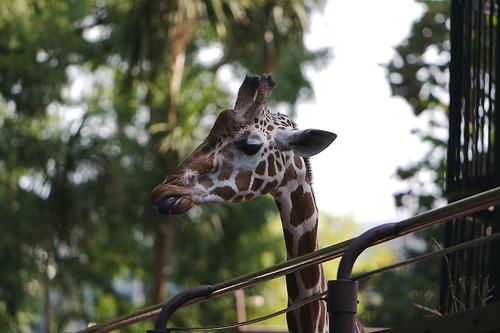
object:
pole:
[324, 220, 365, 332]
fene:
[1, 183, 498, 330]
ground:
[405, 115, 426, 137]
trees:
[1, 0, 336, 332]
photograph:
[0, 0, 500, 332]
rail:
[401, 175, 498, 236]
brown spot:
[235, 171, 253, 191]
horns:
[233, 75, 260, 111]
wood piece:
[233, 287, 249, 328]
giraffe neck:
[269, 185, 329, 333]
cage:
[435, 2, 498, 315]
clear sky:
[300, 0, 420, 219]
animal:
[152, 65, 326, 332]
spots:
[274, 190, 284, 197]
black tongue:
[156, 198, 176, 216]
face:
[149, 107, 279, 215]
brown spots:
[289, 185, 317, 227]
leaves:
[386, 3, 447, 115]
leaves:
[226, 0, 333, 65]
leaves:
[0, 0, 93, 78]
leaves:
[0, 113, 60, 264]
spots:
[234, 167, 253, 194]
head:
[148, 73, 338, 217]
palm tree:
[90, 0, 330, 321]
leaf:
[33, 104, 138, 233]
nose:
[160, 175, 179, 186]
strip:
[171, 128, 220, 175]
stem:
[149, 61, 188, 301]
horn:
[256, 72, 278, 102]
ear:
[275, 127, 335, 156]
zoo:
[9, 29, 444, 333]